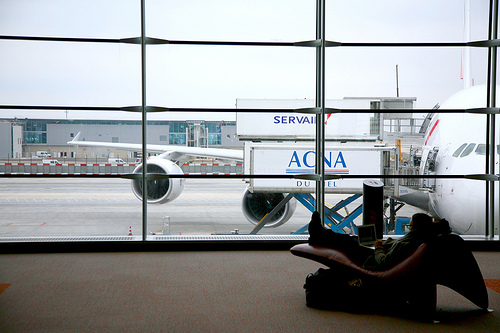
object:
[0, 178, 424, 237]
pavement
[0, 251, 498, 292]
carpeting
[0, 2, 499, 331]
room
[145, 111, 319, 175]
windows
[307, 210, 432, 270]
person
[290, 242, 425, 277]
cushion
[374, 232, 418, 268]
shirt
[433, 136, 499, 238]
front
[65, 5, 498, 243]
plane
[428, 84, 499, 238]
body